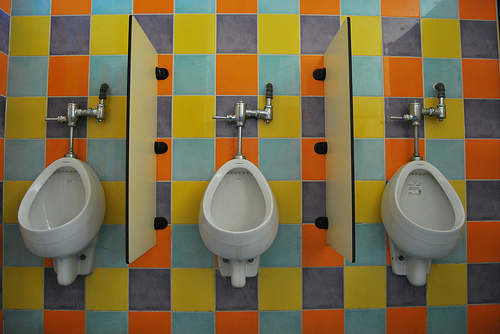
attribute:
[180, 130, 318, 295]
urinal — white, ceramic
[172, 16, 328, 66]
wall — multi colored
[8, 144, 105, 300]
urinal — WHITE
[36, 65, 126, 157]
plumbing — SILVER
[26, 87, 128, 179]
handle — flushes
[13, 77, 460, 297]
urinals — white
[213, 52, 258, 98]
square — orange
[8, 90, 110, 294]
urinal — white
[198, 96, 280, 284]
urinal — white 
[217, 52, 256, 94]
square — yellow , purple , orange 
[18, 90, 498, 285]
urinals — 3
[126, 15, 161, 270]
urinal divider — light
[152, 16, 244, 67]
square — blue